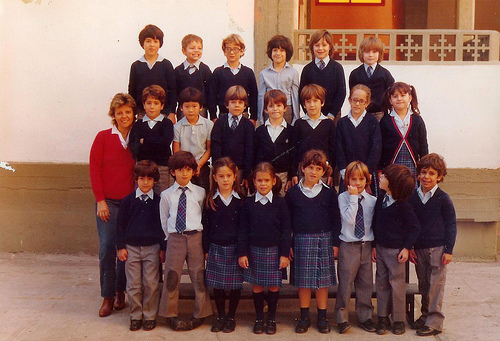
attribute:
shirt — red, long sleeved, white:
[95, 140, 129, 196]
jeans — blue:
[94, 223, 120, 296]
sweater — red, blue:
[99, 153, 120, 181]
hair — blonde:
[115, 93, 134, 104]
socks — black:
[301, 306, 327, 318]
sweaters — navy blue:
[304, 63, 389, 84]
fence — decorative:
[302, 12, 495, 39]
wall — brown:
[263, 0, 286, 21]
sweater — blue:
[386, 120, 398, 152]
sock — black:
[250, 288, 266, 319]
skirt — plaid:
[293, 232, 337, 286]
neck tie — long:
[183, 67, 194, 87]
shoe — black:
[266, 320, 276, 335]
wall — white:
[451, 75, 498, 138]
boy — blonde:
[176, 31, 206, 89]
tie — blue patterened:
[365, 62, 375, 76]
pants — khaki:
[341, 242, 372, 318]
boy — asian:
[174, 85, 218, 153]